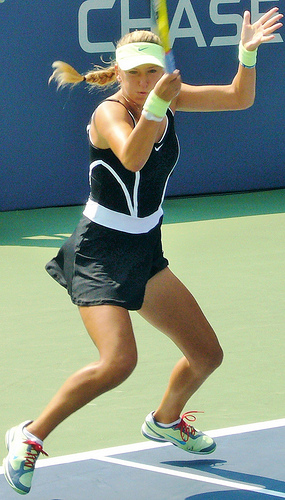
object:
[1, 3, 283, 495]
woman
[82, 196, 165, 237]
band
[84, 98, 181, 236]
shirt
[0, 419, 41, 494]
shoe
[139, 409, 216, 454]
shoe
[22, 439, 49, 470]
lace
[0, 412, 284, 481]
stripe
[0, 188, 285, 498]
tennis court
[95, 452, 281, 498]
stripe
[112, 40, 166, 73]
hat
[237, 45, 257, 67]
wrist band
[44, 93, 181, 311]
tennis dress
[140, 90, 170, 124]
wrist band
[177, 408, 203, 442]
lace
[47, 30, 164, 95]
hair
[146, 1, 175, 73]
racket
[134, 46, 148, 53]
logo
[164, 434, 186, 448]
logo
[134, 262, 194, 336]
thigh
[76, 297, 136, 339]
thigh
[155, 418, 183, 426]
sock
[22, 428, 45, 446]
sock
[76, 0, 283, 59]
name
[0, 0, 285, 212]
wall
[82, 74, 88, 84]
hair band